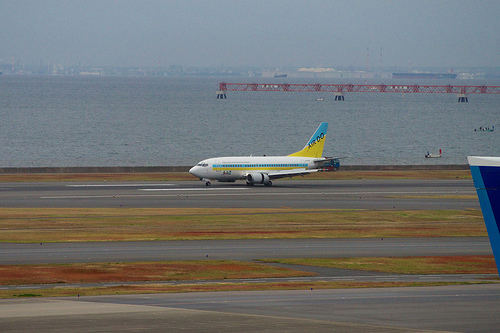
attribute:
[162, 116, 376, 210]
airplane — yellow, blue, white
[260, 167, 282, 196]
wheel — black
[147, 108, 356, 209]
plane — driving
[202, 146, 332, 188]
stripes — blue, yellow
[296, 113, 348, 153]
tail — painted blue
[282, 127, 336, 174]
tail — painted yellow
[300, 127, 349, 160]
word — Air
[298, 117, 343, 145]
word — Do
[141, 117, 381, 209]
airplane — white, blue striped, yellow striped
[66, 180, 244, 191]
lines — white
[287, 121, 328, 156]
tail fin — yellow, blue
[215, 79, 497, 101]
structure — red, metal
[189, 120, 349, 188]
airplane — dual engine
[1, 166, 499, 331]
runway — red, yellow, grey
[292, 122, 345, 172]
tail — yellow, blue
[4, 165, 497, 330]
airplane runways — three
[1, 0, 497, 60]
sky — foggy, grey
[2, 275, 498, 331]
runway — first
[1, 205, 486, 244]
grass — brown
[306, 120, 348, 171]
tail wing — light blue, yellow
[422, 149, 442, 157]
bouy — red, floating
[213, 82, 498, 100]
structure — blue, white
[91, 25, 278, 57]
sky — hazy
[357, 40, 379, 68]
pillar — red, tall, white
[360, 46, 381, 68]
pillar — red, tall, white